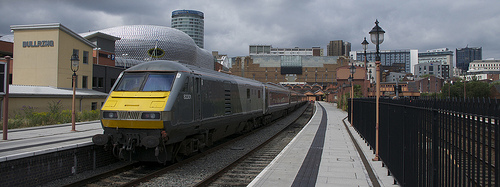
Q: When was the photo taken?
A: During the day.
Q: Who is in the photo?
A: No one.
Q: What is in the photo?
A: A train.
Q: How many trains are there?
A: One.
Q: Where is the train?
A: On the tracks.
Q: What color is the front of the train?
A: Yellow.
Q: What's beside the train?
A: Lights.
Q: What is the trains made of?
A: Metal.